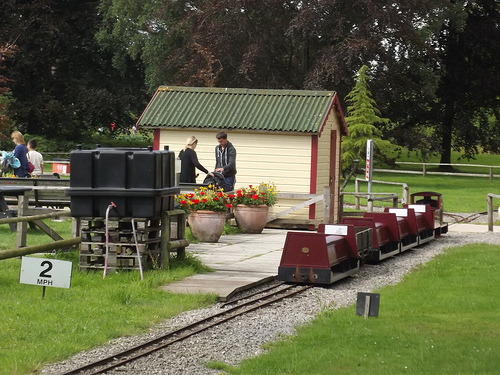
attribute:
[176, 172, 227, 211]
flowers — red, yellow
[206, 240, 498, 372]
grass — green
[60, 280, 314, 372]
train track — small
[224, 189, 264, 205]
flowers — red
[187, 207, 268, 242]
pots — large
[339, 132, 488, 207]
fence — wooden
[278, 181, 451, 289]
kiddie train — small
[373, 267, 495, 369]
grass — green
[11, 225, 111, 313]
sign — black, white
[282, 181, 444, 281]
train — red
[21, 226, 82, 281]
number — 2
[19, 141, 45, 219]
person — walking away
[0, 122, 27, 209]
person — walking away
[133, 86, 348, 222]
building — small